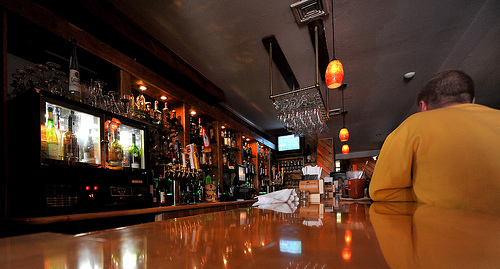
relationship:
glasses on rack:
[276, 95, 331, 136] [262, 18, 330, 125]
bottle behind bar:
[66, 36, 82, 100] [1, 194, 389, 269]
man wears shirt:
[368, 68, 499, 209] [368, 105, 499, 212]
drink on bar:
[347, 160, 368, 197] [1, 194, 389, 269]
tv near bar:
[275, 135, 302, 151] [1, 194, 389, 269]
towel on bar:
[252, 187, 300, 210] [1, 194, 389, 269]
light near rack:
[325, 60, 344, 90] [262, 18, 330, 125]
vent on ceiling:
[290, 0, 330, 27] [106, 1, 499, 160]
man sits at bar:
[368, 68, 499, 209] [1, 194, 389, 269]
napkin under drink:
[341, 196, 371, 201] [347, 160, 368, 197]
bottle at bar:
[66, 36, 82, 100] [1, 194, 389, 269]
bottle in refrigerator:
[129, 134, 141, 169] [1, 87, 152, 217]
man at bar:
[368, 68, 499, 209] [1, 194, 389, 269]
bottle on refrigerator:
[66, 36, 82, 100] [1, 87, 152, 217]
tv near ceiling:
[275, 135, 302, 151] [106, 1, 499, 160]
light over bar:
[325, 60, 344, 90] [1, 194, 389, 269]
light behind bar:
[140, 85, 148, 92] [1, 194, 389, 269]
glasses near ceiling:
[276, 95, 331, 136] [106, 1, 499, 160]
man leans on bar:
[368, 68, 499, 209] [1, 194, 389, 269]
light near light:
[325, 60, 344, 90] [340, 129, 349, 142]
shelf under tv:
[278, 155, 305, 174] [275, 135, 302, 151]